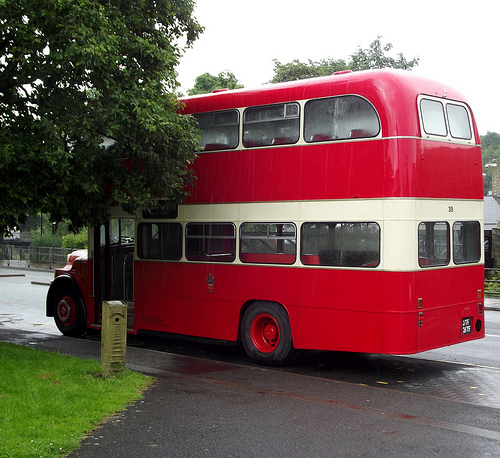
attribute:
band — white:
[117, 202, 497, 276]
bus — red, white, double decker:
[36, 57, 493, 377]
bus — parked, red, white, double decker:
[44, 66, 481, 354]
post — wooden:
[97, 292, 134, 377]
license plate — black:
[452, 314, 477, 334]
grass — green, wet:
[20, 337, 139, 440]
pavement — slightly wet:
[125, 348, 472, 450]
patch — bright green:
[12, 342, 149, 435]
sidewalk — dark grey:
[157, 322, 482, 451]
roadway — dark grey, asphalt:
[14, 259, 480, 414]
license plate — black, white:
[457, 313, 474, 335]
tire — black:
[241, 298, 291, 362]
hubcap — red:
[250, 313, 279, 351]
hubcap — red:
[55, 292, 75, 329]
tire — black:
[45, 287, 81, 336]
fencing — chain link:
[15, 237, 56, 269]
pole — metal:
[104, 297, 130, 375]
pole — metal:
[103, 297, 132, 381]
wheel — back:
[241, 310, 307, 374]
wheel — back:
[233, 300, 298, 372]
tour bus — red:
[44, 65, 488, 368]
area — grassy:
[7, 345, 167, 448]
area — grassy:
[3, 343, 142, 455]